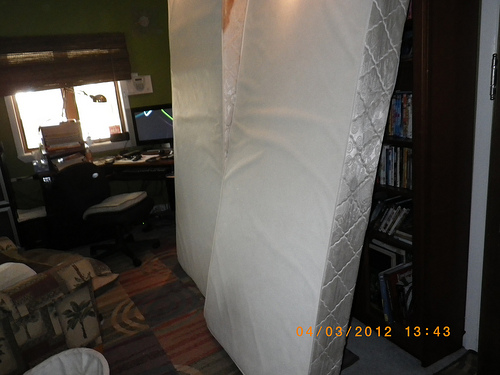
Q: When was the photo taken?
A: In 2012.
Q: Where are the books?
A: On the shelf.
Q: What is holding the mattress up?
A: The bookcase.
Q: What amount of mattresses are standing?
A: Two.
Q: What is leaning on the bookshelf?
A: Mattresses.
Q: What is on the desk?
A: Computer monitor.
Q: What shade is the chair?
A: Black.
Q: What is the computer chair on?
A: Wheels.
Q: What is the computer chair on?
A: Wheels.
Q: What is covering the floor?
A: A rug.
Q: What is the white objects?
A: Bedding box springs.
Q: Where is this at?
A: A house.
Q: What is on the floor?
A: Carpet.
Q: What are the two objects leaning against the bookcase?
A: Mattresses.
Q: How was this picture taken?
A: With a camera.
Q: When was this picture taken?
A: April 3, 2012.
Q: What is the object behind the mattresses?
A: A bookcase.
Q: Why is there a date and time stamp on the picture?
A: The picture was shot with a videorecorder.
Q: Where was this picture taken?
A: In a house.